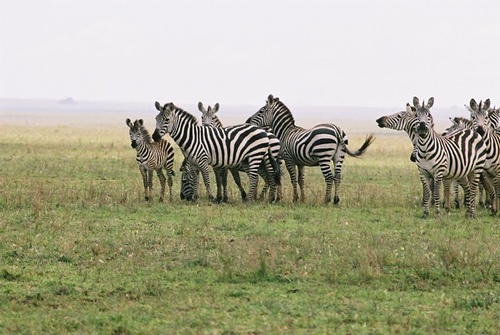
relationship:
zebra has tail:
[246, 93, 376, 203] [337, 130, 375, 157]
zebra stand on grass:
[412, 95, 490, 223] [0, 99, 498, 334]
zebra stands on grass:
[412, 95, 490, 223] [0, 99, 498, 334]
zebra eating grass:
[180, 158, 201, 203] [0, 99, 498, 334]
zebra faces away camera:
[411, 96, 488, 213] [248, 331, 251, 335]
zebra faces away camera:
[246, 93, 376, 203] [248, 331, 251, 335]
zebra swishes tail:
[246, 93, 376, 203] [337, 130, 375, 157]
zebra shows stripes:
[153, 101, 282, 203] [172, 112, 267, 163]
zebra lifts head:
[376, 104, 415, 136] [378, 102, 414, 132]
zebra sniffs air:
[376, 104, 415, 136] [1, 1, 500, 131]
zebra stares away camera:
[411, 96, 488, 213] [248, 331, 251, 335]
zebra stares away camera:
[468, 99, 499, 215] [248, 331, 251, 335]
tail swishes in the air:
[337, 130, 375, 157] [0, 0, 495, 330]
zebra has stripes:
[153, 101, 282, 203] [172, 112, 267, 163]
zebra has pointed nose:
[376, 104, 415, 136] [376, 115, 389, 129]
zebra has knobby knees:
[125, 116, 176, 201] [143, 181, 176, 189]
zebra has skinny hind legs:
[125, 116, 176, 201] [140, 166, 176, 203]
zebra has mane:
[451, 115, 477, 136] [453, 117, 472, 125]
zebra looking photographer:
[412, 95, 490, 223] [231, 328, 239, 335]